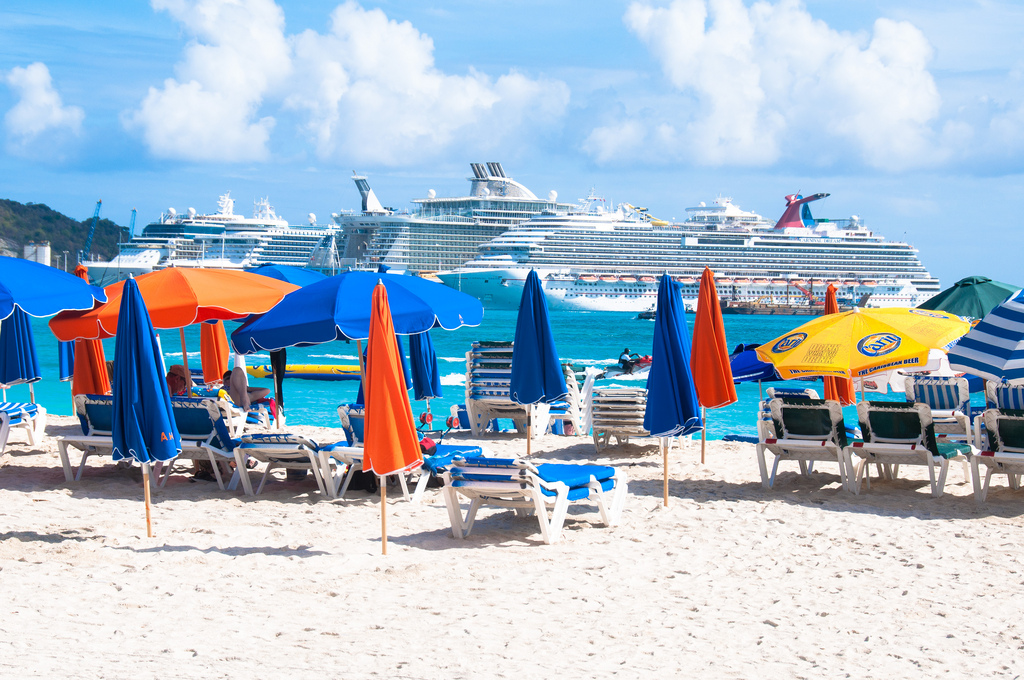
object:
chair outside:
[745, 375, 860, 500]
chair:
[427, 449, 631, 554]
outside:
[5, 2, 1024, 679]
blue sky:
[0, 0, 1009, 193]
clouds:
[599, 13, 974, 173]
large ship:
[49, 149, 965, 330]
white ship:
[420, 186, 967, 327]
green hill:
[0, 191, 141, 269]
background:
[0, 0, 1024, 268]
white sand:
[0, 462, 1024, 680]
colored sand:
[0, 403, 1022, 680]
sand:
[0, 416, 1023, 680]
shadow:
[617, 466, 1024, 526]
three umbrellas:
[498, 261, 738, 444]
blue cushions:
[439, 450, 624, 504]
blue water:
[0, 290, 1024, 441]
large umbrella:
[347, 274, 440, 563]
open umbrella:
[745, 296, 986, 389]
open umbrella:
[37, 254, 314, 350]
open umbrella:
[219, 263, 499, 364]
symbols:
[850, 327, 911, 362]